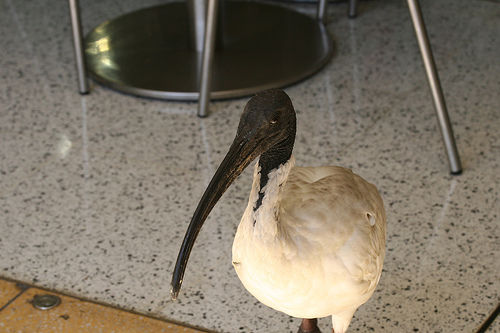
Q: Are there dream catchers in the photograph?
A: No, there are no dream catchers.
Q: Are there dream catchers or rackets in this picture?
A: No, there are no dream catchers or rackets.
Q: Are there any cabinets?
A: No, there are no cabinets.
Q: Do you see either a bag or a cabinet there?
A: No, there are no cabinets or bags.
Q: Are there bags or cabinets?
A: No, there are no cabinets or bags.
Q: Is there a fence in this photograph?
A: No, there are no fences.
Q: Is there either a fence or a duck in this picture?
A: No, there are no fences or ducks.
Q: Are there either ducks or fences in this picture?
A: No, there are no fences or ducks.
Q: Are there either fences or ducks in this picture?
A: No, there are no fences or ducks.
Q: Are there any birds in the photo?
A: Yes, there is a bird.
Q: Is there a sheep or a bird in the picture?
A: Yes, there is a bird.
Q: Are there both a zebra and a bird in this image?
A: No, there is a bird but no zebras.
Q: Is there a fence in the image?
A: No, there are no fences.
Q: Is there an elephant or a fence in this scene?
A: No, there are no fences or elephants.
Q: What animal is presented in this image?
A: The animal is a bird.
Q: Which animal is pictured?
A: The animal is a bird.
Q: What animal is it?
A: The animal is a bird.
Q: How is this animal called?
A: This is a bird.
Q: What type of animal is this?
A: This is a bird.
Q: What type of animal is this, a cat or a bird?
A: This is a bird.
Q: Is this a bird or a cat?
A: This is a bird.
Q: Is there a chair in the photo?
A: Yes, there is a chair.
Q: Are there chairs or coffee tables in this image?
A: Yes, there is a chair.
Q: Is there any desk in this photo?
A: No, there are no desks.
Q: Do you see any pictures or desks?
A: No, there are no desks or pictures.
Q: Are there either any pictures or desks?
A: No, there are no desks or pictures.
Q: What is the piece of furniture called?
A: The piece of furniture is a chair.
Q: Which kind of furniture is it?
A: The piece of furniture is a chair.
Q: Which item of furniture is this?
A: That is a chair.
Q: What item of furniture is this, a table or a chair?
A: That is a chair.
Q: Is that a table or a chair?
A: That is a chair.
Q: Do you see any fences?
A: No, there are no fences.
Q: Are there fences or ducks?
A: No, there are no fences or ducks.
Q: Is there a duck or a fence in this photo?
A: No, there are no fences or ducks.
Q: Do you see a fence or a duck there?
A: No, there are no fences or ducks.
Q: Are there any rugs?
A: No, there are no rugs.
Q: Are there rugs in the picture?
A: No, there are no rugs.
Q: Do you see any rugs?
A: No, there are no rugs.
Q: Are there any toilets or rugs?
A: No, there are no rugs or toilets.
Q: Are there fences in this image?
A: No, there are no fences.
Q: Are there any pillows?
A: No, there are no pillows.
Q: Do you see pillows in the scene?
A: No, there are no pillows.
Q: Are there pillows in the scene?
A: No, there are no pillows.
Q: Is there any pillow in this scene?
A: No, there are no pillows.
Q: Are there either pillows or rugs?
A: No, there are no pillows or rugs.